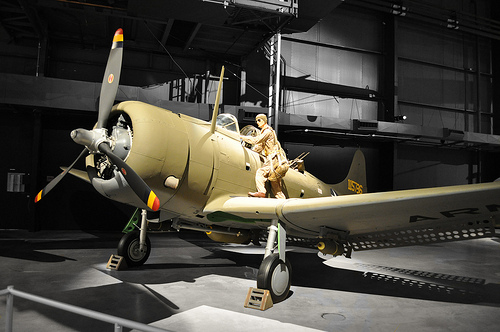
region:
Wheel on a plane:
[248, 246, 295, 302]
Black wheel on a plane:
[116, 220, 158, 269]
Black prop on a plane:
[33, 70, 176, 212]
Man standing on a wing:
[236, 112, 311, 224]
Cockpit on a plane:
[203, 104, 295, 159]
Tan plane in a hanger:
[71, 88, 422, 261]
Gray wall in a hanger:
[166, 11, 405, 153]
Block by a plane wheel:
[240, 283, 287, 323]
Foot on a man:
[243, 176, 277, 204]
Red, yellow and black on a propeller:
[135, 185, 171, 221]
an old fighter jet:
[39, 63, 497, 288]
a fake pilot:
[241, 110, 294, 200]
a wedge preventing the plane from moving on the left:
[239, 284, 270, 302]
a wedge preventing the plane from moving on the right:
[99, 248, 146, 279]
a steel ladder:
[262, 40, 287, 147]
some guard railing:
[3, 267, 140, 330]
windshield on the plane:
[203, 101, 243, 136]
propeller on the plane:
[38, 27, 153, 229]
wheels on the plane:
[102, 220, 315, 292]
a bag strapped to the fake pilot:
[264, 143, 316, 184]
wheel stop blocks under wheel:
[241, 282, 281, 315]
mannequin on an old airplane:
[234, 107, 301, 199]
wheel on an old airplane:
[248, 231, 301, 300]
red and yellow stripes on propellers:
[131, 183, 166, 217]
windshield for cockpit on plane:
[207, 96, 244, 136]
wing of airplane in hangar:
[232, 170, 496, 270]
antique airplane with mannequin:
[42, 24, 484, 272]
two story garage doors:
[281, 8, 492, 234]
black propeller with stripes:
[26, 22, 169, 232]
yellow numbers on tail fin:
[344, 177, 372, 194]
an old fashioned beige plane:
[34, 26, 498, 303]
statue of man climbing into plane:
[237, 112, 290, 199]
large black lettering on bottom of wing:
[406, 201, 497, 228]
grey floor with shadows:
[9, 234, 497, 329]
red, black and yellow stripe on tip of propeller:
[109, 27, 124, 49]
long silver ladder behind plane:
[266, 30, 281, 128]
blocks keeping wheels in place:
[105, 253, 274, 312]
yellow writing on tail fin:
[345, 176, 365, 193]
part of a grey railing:
[1, 283, 168, 330]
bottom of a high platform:
[0, 0, 300, 70]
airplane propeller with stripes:
[25, 13, 175, 234]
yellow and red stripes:
[139, 186, 165, 217]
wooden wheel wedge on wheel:
[241, 272, 277, 315]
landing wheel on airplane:
[246, 238, 304, 307]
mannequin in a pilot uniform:
[243, 108, 288, 200]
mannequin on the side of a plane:
[234, 107, 294, 204]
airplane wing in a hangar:
[250, 181, 480, 259]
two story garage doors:
[288, 17, 473, 217]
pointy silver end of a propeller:
[65, 123, 95, 149]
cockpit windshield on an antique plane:
[206, 107, 246, 137]